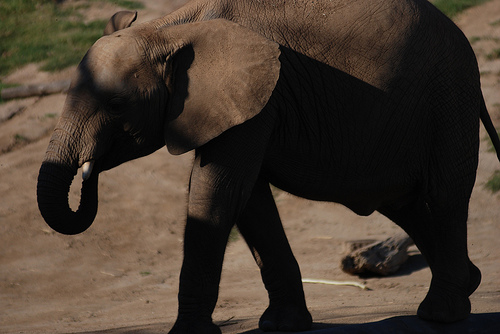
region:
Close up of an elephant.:
[17, 3, 491, 325]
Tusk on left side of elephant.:
[70, 138, 101, 181]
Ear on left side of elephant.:
[158, 14, 290, 160]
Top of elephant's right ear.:
[95, 5, 149, 35]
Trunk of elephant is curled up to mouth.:
[24, 115, 115, 233]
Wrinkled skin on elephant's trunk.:
[48, 105, 99, 163]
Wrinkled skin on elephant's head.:
[131, 20, 175, 62]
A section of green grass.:
[4, 4, 86, 62]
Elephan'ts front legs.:
[171, 153, 308, 332]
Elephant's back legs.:
[356, 175, 493, 329]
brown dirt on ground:
[7, 278, 44, 309]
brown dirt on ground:
[74, 282, 115, 317]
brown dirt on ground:
[136, 247, 166, 297]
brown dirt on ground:
[229, 281, 259, 320]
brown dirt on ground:
[324, 291, 385, 321]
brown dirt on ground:
[291, 207, 342, 253]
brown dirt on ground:
[115, 207, 156, 253]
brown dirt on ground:
[136, 169, 163, 201]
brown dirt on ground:
[0, 204, 70, 262]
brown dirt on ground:
[3, 165, 23, 195]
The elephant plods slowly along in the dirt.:
[36, 2, 446, 332]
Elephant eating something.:
[23, 6, 163, 248]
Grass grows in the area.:
[2, 0, 103, 70]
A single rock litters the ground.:
[344, 235, 414, 281]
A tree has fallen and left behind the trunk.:
[0, 70, 72, 104]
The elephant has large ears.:
[160, 28, 284, 160]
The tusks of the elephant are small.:
[77, 151, 97, 183]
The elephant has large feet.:
[415, 272, 490, 329]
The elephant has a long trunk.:
[36, 109, 104, 237]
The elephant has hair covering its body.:
[181, 156, 198, 254]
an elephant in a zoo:
[32, 0, 498, 329]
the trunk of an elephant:
[26, 132, 108, 242]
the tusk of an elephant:
[76, 156, 95, 181]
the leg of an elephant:
[158, 197, 247, 332]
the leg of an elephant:
[246, 214, 318, 328]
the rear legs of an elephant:
[393, 208, 497, 320]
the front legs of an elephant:
[171, 168, 305, 330]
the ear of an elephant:
[163, 20, 283, 157]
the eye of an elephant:
[103, 93, 128, 117]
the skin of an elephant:
[303, 16, 434, 166]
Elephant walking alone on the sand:
[36, 2, 498, 330]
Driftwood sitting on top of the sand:
[341, 233, 423, 277]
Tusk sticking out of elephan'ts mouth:
[81, 159, 90, 179]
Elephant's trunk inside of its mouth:
[36, 73, 100, 236]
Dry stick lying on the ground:
[299, 278, 368, 289]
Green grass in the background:
[3, 4, 108, 76]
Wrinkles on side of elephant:
[173, 0, 477, 187]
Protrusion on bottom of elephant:
[341, 195, 378, 216]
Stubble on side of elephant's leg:
[173, 155, 195, 330]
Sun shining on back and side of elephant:
[156, 3, 425, 152]